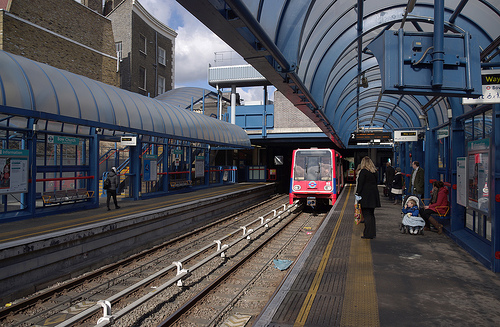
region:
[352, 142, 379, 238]
a person at the station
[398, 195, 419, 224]
a person at the station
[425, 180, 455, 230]
a person at the station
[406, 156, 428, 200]
a person at the station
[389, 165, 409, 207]
a person at the station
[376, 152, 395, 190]
a person at the station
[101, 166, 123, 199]
a person at the station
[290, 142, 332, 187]
a window in a train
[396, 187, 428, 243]
a young baby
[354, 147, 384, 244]
a bland woman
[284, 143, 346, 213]
red train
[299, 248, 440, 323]
train platform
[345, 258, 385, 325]
yellow line on train platform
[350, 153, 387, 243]
woman standing on train platform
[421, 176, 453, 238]
person sitting on bench on train platform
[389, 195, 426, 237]
child in stroller on train platform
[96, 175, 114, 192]
black bookbag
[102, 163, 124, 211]
person walking along train platform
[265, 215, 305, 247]
metal train tracks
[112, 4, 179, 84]
four windows on side of building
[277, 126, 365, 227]
oncoming train is red and blue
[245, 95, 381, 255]
oncoming train is red and blue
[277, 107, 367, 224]
red train on tracks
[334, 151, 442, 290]
people waiting for train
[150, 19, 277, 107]
sky is partly cloudy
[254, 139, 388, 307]
train is parked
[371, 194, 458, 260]
little girl in blue dress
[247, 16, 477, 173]
ceiling is blue glass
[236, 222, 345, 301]
garbage on train track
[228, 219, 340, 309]
blue garbage on tracks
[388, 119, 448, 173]
white and black sign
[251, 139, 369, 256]
red train with blue on it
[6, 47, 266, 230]
arched covering for passengers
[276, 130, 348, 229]
red passenger train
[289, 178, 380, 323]
yellow caution line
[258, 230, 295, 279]
refuse on train tracks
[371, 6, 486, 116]
hanging blue schedule display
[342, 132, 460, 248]
several people waiting for a train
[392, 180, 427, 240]
small baby in a stroller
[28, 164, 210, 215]
metal benches on a platform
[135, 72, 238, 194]
covered staircase leading to a street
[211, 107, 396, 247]
tunnel for passenger trains